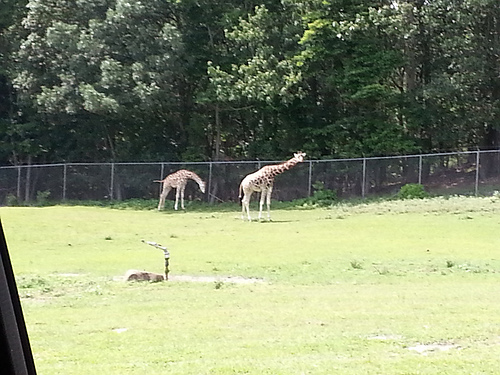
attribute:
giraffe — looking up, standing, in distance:
[238, 149, 307, 223]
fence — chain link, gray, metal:
[1, 146, 499, 206]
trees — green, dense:
[0, 0, 499, 201]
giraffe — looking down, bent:
[153, 169, 206, 211]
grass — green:
[0, 195, 499, 373]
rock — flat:
[124, 269, 165, 283]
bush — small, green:
[392, 182, 430, 201]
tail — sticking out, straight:
[153, 178, 164, 184]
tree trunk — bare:
[115, 183, 126, 201]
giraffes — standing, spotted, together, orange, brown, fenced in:
[153, 150, 306, 224]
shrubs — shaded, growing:
[1, 180, 499, 209]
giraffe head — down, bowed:
[198, 181, 207, 193]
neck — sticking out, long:
[271, 158, 298, 176]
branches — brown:
[1, 0, 499, 166]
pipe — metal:
[139, 236, 170, 280]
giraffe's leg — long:
[244, 187, 253, 220]